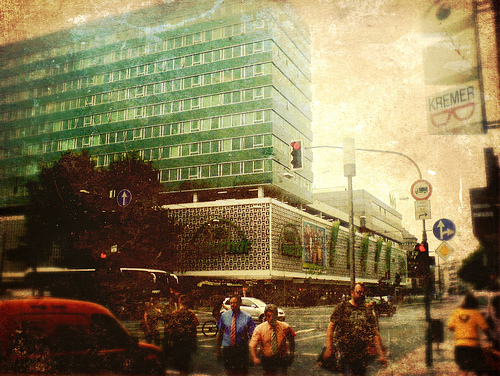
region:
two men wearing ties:
[217, 292, 294, 367]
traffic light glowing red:
[281, 136, 306, 176]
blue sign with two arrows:
[430, 213, 457, 246]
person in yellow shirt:
[437, 290, 487, 361]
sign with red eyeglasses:
[417, 82, 478, 130]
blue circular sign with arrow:
[110, 182, 133, 209]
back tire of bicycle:
[195, 316, 223, 341]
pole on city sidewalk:
[406, 276, 442, 371]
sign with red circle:
[407, 176, 435, 204]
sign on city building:
[292, 217, 337, 280]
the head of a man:
[263, 302, 282, 325]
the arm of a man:
[318, 300, 345, 360]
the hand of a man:
[321, 343, 333, 361]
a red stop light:
[289, 136, 305, 152]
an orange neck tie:
[226, 312, 238, 349]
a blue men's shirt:
[216, 307, 257, 346]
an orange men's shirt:
[246, 318, 298, 360]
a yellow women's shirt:
[444, 306, 488, 347]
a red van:
[0, 295, 170, 374]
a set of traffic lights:
[286, 137, 306, 170]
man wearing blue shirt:
[212, 279, 247, 373]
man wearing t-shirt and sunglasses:
[326, 271, 390, 368]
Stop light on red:
[282, 132, 307, 172]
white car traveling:
[220, 285, 285, 323]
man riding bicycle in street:
[205, 284, 234, 334]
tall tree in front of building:
[27, 142, 177, 283]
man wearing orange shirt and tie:
[247, 299, 306, 374]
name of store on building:
[187, 212, 252, 262]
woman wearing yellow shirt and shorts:
[445, 283, 487, 370]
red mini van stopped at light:
[4, 285, 163, 370]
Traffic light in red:
[284, 128, 306, 173]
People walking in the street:
[128, 277, 498, 369]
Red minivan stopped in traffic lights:
[4, 297, 169, 372]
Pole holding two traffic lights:
[305, 140, 438, 372]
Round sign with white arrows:
[431, 215, 458, 241]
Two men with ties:
[212, 294, 297, 371]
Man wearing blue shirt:
[211, 294, 257, 374]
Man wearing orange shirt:
[248, 302, 308, 374]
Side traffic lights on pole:
[413, 240, 435, 285]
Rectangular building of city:
[1, 0, 325, 205]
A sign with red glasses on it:
[408, 74, 492, 141]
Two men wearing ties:
[207, 285, 304, 372]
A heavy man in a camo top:
[314, 273, 398, 374]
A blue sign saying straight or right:
[428, 210, 468, 250]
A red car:
[11, 286, 159, 374]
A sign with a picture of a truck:
[400, 175, 437, 200]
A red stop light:
[281, 134, 311, 179]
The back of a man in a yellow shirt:
[444, 290, 492, 374]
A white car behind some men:
[206, 281, 288, 328]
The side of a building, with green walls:
[62, 71, 240, 136]